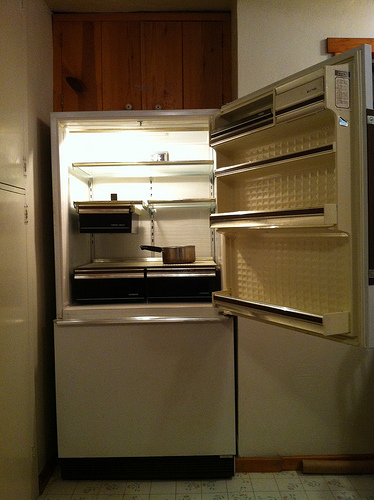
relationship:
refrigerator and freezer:
[56, 113, 217, 307] [62, 313, 239, 465]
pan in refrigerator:
[148, 242, 196, 265] [56, 113, 217, 307]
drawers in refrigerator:
[203, 205, 205, 206] [56, 113, 217, 307]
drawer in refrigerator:
[142, 269, 221, 298] [56, 113, 217, 307]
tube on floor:
[292, 457, 364, 478] [261, 469, 288, 496]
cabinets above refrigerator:
[61, 9, 227, 107] [56, 113, 217, 307]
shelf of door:
[88, 164, 206, 178] [212, 89, 349, 333]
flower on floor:
[88, 484, 138, 496] [261, 469, 288, 496]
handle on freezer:
[52, 317, 224, 328] [62, 313, 239, 465]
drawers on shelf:
[203, 205, 205, 206] [88, 164, 206, 178]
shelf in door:
[88, 164, 206, 178] [212, 89, 349, 333]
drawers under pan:
[203, 205, 205, 206] [148, 242, 196, 265]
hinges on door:
[198, 196, 323, 226] [212, 89, 349, 333]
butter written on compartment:
[285, 80, 325, 93] [261, 80, 327, 106]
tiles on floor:
[244, 473, 282, 496] [261, 469, 288, 496]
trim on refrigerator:
[15, 133, 43, 210] [56, 113, 217, 307]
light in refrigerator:
[84, 132, 144, 149] [56, 113, 217, 307]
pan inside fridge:
[140, 242, 196, 263] [45, 237, 224, 306]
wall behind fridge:
[237, 177, 301, 197] [45, 237, 224, 306]